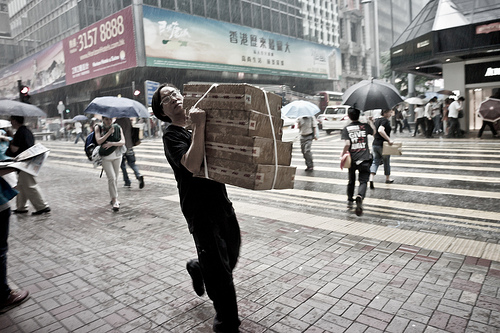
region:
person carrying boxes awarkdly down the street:
[149, 78, 295, 330]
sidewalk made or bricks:
[4, 159, 499, 330]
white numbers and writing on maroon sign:
[63, 8, 134, 83]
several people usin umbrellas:
[286, 79, 498, 212]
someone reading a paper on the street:
[1, 135, 46, 315]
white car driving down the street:
[316, 103, 352, 132]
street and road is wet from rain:
[4, 126, 497, 326]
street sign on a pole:
[55, 98, 67, 141]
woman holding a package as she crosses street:
[366, 105, 407, 190]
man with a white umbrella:
[281, 98, 322, 176]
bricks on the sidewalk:
[275, 246, 395, 289]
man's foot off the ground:
[171, 248, 236, 298]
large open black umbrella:
[336, 70, 439, 137]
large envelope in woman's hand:
[375, 137, 416, 162]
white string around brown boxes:
[202, 80, 293, 198]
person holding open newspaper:
[13, 135, 63, 197]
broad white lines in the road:
[416, 144, 477, 235]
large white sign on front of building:
[160, 13, 338, 76]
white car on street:
[309, 97, 363, 134]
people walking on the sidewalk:
[359, 67, 472, 142]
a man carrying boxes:
[156, 78, 298, 330]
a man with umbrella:
[332, 74, 404, 214]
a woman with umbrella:
[81, 94, 146, 214]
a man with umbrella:
[3, 102, 51, 218]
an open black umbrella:
[340, 75, 401, 110]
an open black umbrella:
[84, 93, 152, 120]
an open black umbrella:
[1, 97, 46, 119]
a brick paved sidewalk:
[2, 159, 499, 331]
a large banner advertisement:
[141, 8, 342, 78]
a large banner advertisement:
[64, 8, 136, 85]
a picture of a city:
[2, 8, 457, 303]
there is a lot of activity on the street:
[19, 54, 481, 230]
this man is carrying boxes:
[151, 78, 298, 320]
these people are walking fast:
[330, 73, 402, 223]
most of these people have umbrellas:
[342, 72, 496, 132]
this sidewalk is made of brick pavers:
[48, 190, 473, 324]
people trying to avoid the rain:
[291, 80, 482, 165]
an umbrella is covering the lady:
[81, 90, 146, 210]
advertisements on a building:
[62, 5, 340, 83]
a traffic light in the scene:
[13, 74, 49, 107]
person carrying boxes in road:
[147, 65, 287, 327]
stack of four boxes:
[197, 83, 302, 213]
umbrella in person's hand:
[347, 77, 391, 114]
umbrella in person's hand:
[86, 96, 150, 122]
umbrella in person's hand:
[1, 102, 42, 116]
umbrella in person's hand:
[285, 100, 323, 125]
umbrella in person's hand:
[478, 100, 498, 124]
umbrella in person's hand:
[406, 94, 428, 106]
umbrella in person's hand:
[433, 88, 451, 98]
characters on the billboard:
[221, 29, 303, 54]